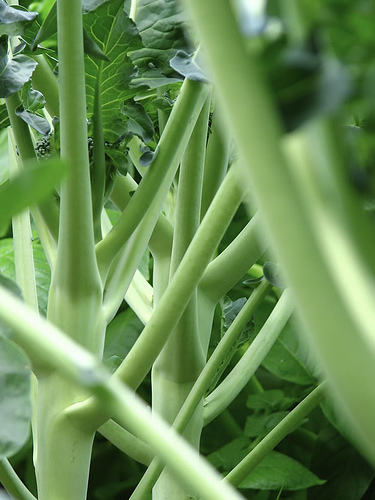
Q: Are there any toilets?
A: No, there are no toilets.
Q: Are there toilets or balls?
A: No, there are no toilets or balls.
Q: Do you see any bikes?
A: No, there are no bikes.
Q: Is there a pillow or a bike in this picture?
A: No, there are no bikes or pillows.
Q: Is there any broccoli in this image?
A: Yes, there is broccoli.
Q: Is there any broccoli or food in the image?
A: Yes, there is broccoli.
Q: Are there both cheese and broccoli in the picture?
A: No, there is broccoli but no cheese.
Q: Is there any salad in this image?
A: No, there is no salad.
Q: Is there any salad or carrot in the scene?
A: No, there are no salad or carrots.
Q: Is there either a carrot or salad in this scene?
A: No, there are no salad or carrots.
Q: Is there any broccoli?
A: Yes, there is broccoli.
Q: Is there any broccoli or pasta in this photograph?
A: Yes, there is broccoli.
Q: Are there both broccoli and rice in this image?
A: No, there is broccoli but no rice.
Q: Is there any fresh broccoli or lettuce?
A: Yes, there is fresh broccoli.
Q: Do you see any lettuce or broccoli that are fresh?
A: Yes, the broccoli is fresh.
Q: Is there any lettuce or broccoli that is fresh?
A: Yes, the broccoli is fresh.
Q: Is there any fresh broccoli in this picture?
A: Yes, there is fresh broccoli.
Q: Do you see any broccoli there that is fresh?
A: Yes, there is broccoli that is fresh.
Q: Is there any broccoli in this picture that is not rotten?
A: Yes, there is fresh broccoli.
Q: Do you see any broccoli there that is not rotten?
A: Yes, there is fresh broccoli.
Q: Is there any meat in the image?
A: No, there is no meat.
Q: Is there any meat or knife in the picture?
A: No, there are no meat or knives.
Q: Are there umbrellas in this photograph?
A: No, there are no umbrellas.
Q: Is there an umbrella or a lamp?
A: No, there are no umbrellas or lamps.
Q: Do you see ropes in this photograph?
A: No, there are no ropes.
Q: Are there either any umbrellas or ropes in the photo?
A: No, there are no ropes or umbrellas.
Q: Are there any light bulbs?
A: No, there are no light bulbs.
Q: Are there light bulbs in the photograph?
A: No, there are no light bulbs.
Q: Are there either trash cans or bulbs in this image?
A: No, there are no bulbs or trash cans.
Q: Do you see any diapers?
A: No, there are no diapers.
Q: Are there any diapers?
A: No, there are no diapers.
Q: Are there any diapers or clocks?
A: No, there are no diapers or clocks.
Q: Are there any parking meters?
A: No, there are no parking meters.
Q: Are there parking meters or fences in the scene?
A: No, there are no parking meters or fences.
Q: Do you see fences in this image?
A: No, there are no fences.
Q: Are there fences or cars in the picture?
A: No, there are no fences or cars.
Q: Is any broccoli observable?
A: Yes, there is broccoli.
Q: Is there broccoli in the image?
A: Yes, there is broccoli.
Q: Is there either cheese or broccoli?
A: Yes, there is broccoli.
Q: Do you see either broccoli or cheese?
A: Yes, there is broccoli.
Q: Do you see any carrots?
A: No, there are no carrots.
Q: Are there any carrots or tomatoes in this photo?
A: No, there are no carrots or tomatoes.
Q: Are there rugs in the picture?
A: No, there are no rugs.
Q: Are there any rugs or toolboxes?
A: No, there are no rugs or toolboxes.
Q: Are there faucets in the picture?
A: No, there are no faucets.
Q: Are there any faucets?
A: No, there are no faucets.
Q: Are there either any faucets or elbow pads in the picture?
A: No, there are no faucets or elbow pads.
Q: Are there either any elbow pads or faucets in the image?
A: No, there are no faucets or elbow pads.